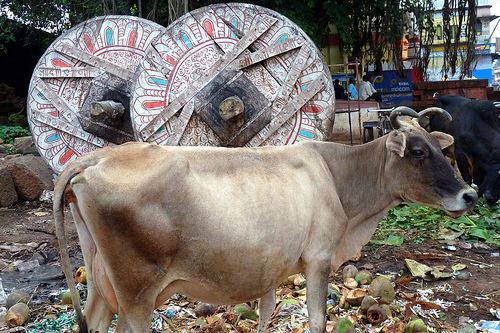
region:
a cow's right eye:
[405, 144, 428, 161]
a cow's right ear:
[386, 130, 408, 157]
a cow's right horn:
[390, 103, 419, 128]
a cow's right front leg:
[297, 240, 342, 331]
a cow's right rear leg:
[71, 195, 178, 332]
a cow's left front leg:
[253, 290, 283, 331]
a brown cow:
[54, 105, 475, 331]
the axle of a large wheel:
[219, 96, 242, 117]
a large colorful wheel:
[136, 3, 338, 143]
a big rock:
[0, 150, 51, 205]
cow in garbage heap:
[55, 111, 462, 328]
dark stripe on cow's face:
[402, 117, 463, 214]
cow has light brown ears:
[381, 124, 415, 166]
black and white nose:
[458, 157, 480, 211]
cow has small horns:
[378, 98, 442, 125]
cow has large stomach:
[188, 148, 313, 282]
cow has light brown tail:
[42, 198, 69, 320]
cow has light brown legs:
[262, 260, 356, 331]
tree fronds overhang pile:
[312, 0, 489, 68]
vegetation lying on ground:
[374, 168, 494, 258]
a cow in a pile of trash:
[25, 108, 478, 330]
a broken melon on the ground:
[366, 272, 399, 300]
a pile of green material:
[376, 199, 498, 261]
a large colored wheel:
[128, 2, 340, 164]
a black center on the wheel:
[192, 72, 279, 139]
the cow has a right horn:
[385, 103, 415, 128]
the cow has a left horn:
[419, 99, 456, 129]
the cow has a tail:
[42, 143, 107, 330]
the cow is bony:
[75, 132, 449, 310]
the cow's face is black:
[393, 120, 475, 207]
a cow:
[66, 109, 472, 331]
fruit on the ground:
[346, 276, 398, 316]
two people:
[343, 75, 375, 96]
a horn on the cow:
[389, 103, 426, 129]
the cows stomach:
[183, 243, 305, 304]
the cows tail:
[56, 230, 97, 330]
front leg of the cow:
[301, 282, 332, 330]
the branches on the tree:
[358, 11, 439, 64]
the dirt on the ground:
[472, 256, 497, 286]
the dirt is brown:
[473, 268, 494, 303]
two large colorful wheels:
[27, 2, 332, 169]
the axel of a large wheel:
[218, 95, 244, 118]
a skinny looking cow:
[55, 105, 481, 331]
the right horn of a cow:
[385, 105, 415, 130]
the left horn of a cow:
[415, 105, 455, 125]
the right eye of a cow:
[410, 144, 427, 161]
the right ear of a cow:
[384, 131, 407, 157]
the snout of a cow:
[433, 162, 478, 221]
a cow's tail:
[53, 150, 98, 332]